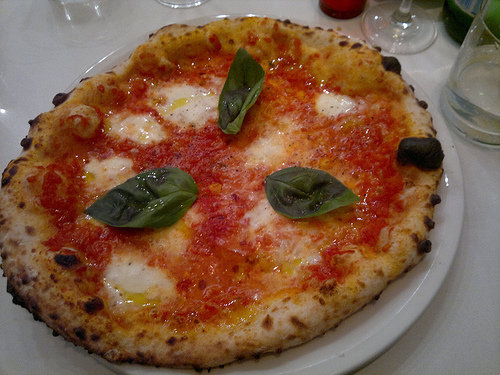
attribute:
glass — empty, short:
[440, 1, 497, 147]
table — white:
[1, 0, 499, 375]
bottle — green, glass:
[441, 1, 500, 48]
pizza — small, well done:
[2, 16, 444, 371]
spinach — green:
[84, 168, 200, 227]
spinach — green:
[217, 44, 264, 135]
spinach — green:
[263, 167, 360, 219]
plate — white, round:
[63, 11, 464, 373]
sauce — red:
[41, 35, 403, 321]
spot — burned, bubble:
[395, 135, 445, 172]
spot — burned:
[428, 191, 442, 204]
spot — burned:
[423, 213, 435, 230]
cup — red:
[317, 1, 366, 21]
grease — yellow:
[115, 284, 157, 309]